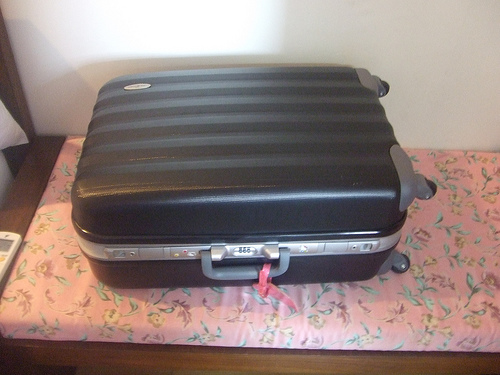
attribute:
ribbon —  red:
[250, 267, 297, 316]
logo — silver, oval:
[120, 80, 153, 92]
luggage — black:
[101, 45, 403, 256]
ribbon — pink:
[232, 253, 318, 323]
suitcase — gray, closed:
[66, 57, 441, 292]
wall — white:
[2, 3, 498, 152]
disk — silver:
[122, 79, 152, 91]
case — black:
[71, 53, 438, 292]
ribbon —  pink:
[252, 262, 298, 314]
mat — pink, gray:
[56, 132, 469, 344]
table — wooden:
[22, 341, 384, 368]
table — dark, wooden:
[3, 132, 498, 372]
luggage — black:
[67, 64, 438, 292]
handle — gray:
[193, 243, 298, 290]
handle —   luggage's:
[198, 249, 303, 276]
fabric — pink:
[48, 138, 493, 374]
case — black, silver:
[90, 68, 423, 301]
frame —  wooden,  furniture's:
[1, 338, 496, 373]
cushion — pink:
[0, 131, 499, 357]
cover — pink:
[3, 130, 499, 354]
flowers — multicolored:
[0, 135, 499, 352]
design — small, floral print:
[4, 130, 499, 350]